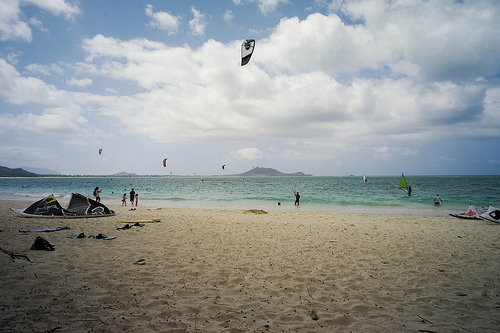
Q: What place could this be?
A: It is a beach.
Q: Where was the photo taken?
A: It was taken at the beach.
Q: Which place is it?
A: It is a beach.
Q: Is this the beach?
A: Yes, it is the beach.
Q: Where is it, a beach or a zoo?
A: It is a beach.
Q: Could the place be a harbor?
A: No, it is a beach.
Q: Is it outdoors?
A: Yes, it is outdoors.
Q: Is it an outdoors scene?
A: Yes, it is outdoors.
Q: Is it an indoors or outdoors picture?
A: It is outdoors.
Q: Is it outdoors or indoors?
A: It is outdoors.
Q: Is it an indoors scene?
A: No, it is outdoors.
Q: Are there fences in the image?
A: No, there are no fences.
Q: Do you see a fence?
A: No, there are no fences.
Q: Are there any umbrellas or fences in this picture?
A: No, there are no fences or umbrellas.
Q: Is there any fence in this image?
A: No, there are no fences.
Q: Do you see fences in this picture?
A: No, there are no fences.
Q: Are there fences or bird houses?
A: No, there are no fences or bird houses.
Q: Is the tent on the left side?
A: Yes, the tent is on the left of the image.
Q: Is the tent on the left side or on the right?
A: The tent is on the left of the image.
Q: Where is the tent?
A: The tent is on the beach.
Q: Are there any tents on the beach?
A: Yes, there is a tent on the beach.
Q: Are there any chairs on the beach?
A: No, there is a tent on the beach.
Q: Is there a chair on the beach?
A: No, there is a tent on the beach.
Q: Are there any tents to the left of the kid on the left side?
A: Yes, there is a tent to the left of the kid.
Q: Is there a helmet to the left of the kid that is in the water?
A: No, there is a tent to the left of the kid.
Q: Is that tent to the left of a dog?
A: No, the tent is to the left of the child.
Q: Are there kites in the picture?
A: Yes, there is a kite.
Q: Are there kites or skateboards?
A: Yes, there is a kite.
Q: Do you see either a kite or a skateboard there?
A: Yes, there is a kite.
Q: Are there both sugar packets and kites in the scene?
A: No, there is a kite but no sugar packets.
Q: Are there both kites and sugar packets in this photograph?
A: No, there is a kite but no sugar packets.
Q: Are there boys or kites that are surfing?
A: Yes, the kite is surfing.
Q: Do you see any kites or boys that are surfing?
A: Yes, the kite is surfing.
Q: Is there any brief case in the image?
A: No, there are no briefcases.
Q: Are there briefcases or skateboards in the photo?
A: No, there are no briefcases or skateboards.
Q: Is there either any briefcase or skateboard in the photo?
A: No, there are no briefcases or skateboards.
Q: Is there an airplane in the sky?
A: No, there is a kite in the sky.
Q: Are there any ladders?
A: No, there are no ladders.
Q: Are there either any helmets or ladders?
A: No, there are no ladders or helmets.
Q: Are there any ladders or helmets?
A: No, there are no ladders or helmets.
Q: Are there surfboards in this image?
A: Yes, there is a surfboard.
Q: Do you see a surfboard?
A: Yes, there is a surfboard.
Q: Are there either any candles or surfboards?
A: Yes, there is a surfboard.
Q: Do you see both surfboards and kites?
A: Yes, there are both a surfboard and a kite.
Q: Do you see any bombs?
A: No, there are no bombs.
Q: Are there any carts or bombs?
A: No, there are no bombs or carts.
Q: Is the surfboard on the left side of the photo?
A: Yes, the surfboard is on the left of the image.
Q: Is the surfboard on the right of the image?
A: No, the surfboard is on the left of the image.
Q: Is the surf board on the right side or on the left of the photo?
A: The surf board is on the left of the image.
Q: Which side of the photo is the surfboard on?
A: The surfboard is on the left of the image.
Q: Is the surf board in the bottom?
A: Yes, the surf board is in the bottom of the image.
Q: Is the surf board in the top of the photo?
A: No, the surf board is in the bottom of the image.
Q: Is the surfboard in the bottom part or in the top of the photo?
A: The surfboard is in the bottom of the image.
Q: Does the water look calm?
A: Yes, the water is calm.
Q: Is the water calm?
A: Yes, the water is calm.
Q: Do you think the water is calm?
A: Yes, the water is calm.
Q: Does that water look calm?
A: Yes, the water is calm.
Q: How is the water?
A: The water is calm.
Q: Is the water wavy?
A: No, the water is calm.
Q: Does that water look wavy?
A: No, the water is calm.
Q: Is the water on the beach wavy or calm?
A: The water is calm.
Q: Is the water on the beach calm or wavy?
A: The water is calm.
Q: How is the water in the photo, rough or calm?
A: The water is calm.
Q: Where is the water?
A: The water is on the beach.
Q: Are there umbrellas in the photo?
A: No, there are no umbrellas.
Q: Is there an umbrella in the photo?
A: No, there are no umbrellas.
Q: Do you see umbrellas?
A: No, there are no umbrellas.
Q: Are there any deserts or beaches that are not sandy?
A: No, there is a beach but it is sandy.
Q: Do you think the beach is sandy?
A: Yes, the beach is sandy.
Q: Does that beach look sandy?
A: Yes, the beach is sandy.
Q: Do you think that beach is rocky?
A: No, the beach is sandy.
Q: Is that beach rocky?
A: No, the beach is sandy.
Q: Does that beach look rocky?
A: No, the beach is sandy.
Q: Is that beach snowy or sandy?
A: The beach is sandy.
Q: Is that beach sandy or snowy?
A: The beach is sandy.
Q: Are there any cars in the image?
A: No, there are no cars.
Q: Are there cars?
A: No, there are no cars.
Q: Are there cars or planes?
A: No, there are no cars or planes.